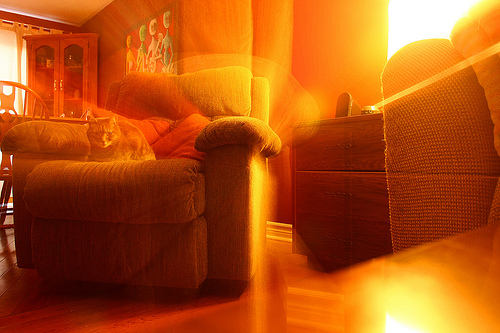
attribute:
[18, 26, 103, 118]
corner cabinet — brown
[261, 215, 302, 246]
baseboard — white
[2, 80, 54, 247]
chair — wooden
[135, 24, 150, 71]
alien — green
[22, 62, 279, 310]
chair — grey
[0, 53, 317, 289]
pillows — orange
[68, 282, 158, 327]
floor — wooden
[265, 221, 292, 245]
baseboard — white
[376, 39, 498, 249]
arm — checker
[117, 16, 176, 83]
art — framed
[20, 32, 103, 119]
cabinet — china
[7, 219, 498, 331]
floor — wooden, brown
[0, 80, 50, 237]
chair — wooden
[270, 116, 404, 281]
cabinet — brown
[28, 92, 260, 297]
easy chair — stuffed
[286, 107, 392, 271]
table — wooden